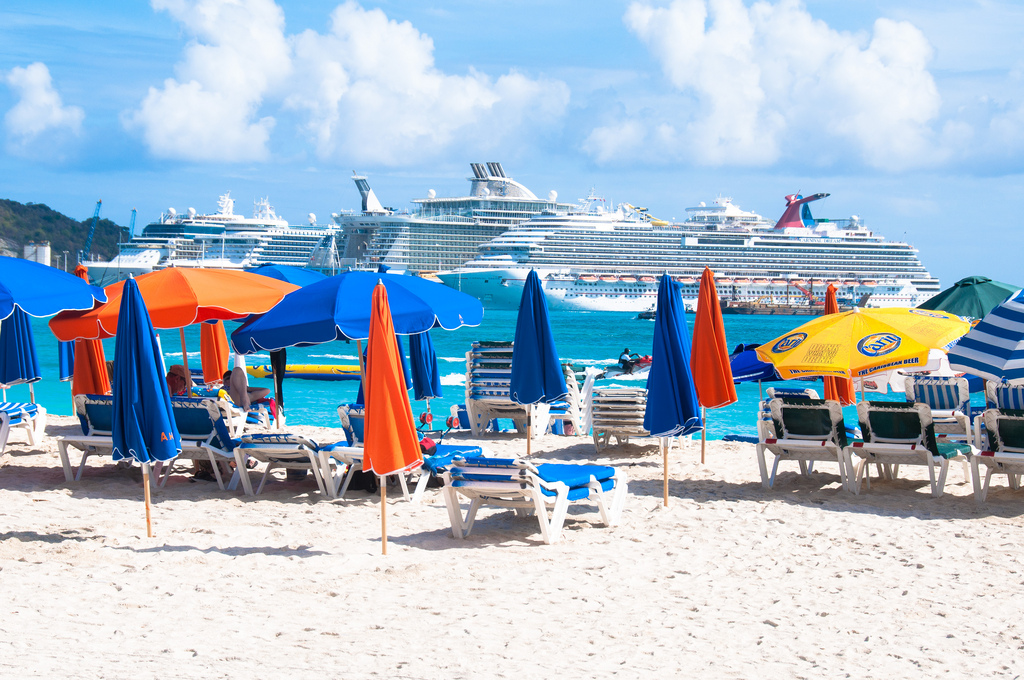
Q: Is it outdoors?
A: Yes, it is outdoors.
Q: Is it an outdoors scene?
A: Yes, it is outdoors.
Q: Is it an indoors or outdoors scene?
A: It is outdoors.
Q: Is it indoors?
A: No, it is outdoors.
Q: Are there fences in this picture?
A: No, there are no fences.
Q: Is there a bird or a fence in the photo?
A: No, there are no fences or birds.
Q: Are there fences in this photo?
A: No, there are no fences.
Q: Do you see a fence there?
A: No, there are no fences.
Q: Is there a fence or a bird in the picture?
A: No, there are no fences or birds.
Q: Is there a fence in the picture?
A: No, there are no fences.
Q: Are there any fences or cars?
A: No, there are no fences or cars.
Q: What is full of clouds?
A: The sky is full of clouds.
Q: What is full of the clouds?
A: The sky is full of clouds.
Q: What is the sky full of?
A: The sky is full of clouds.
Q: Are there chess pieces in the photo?
A: No, there are no chess pieces.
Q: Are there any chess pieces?
A: No, there are no chess pieces.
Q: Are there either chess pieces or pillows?
A: No, there are no chess pieces or pillows.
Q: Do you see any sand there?
A: Yes, there is sand.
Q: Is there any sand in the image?
A: Yes, there is sand.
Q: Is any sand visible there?
A: Yes, there is sand.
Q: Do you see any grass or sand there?
A: Yes, there is sand.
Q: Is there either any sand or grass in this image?
A: Yes, there is sand.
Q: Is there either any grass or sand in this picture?
A: Yes, there is sand.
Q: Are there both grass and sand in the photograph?
A: No, there is sand but no grass.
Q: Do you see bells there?
A: No, there are no bells.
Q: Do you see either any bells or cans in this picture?
A: No, there are no bells or cans.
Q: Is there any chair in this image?
A: Yes, there is a chair.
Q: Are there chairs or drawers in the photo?
A: Yes, there is a chair.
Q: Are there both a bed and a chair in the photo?
A: No, there is a chair but no beds.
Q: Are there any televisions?
A: No, there are no televisions.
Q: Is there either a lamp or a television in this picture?
A: No, there are no televisions or lamps.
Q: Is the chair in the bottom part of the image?
A: Yes, the chair is in the bottom of the image.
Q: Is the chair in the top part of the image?
A: No, the chair is in the bottom of the image.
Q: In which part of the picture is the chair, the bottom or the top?
A: The chair is in the bottom of the image.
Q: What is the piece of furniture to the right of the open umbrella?
A: The piece of furniture is a chair.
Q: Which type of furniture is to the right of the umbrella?
A: The piece of furniture is a chair.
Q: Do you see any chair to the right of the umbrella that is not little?
A: Yes, there is a chair to the right of the umbrella.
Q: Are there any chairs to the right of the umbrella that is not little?
A: Yes, there is a chair to the right of the umbrella.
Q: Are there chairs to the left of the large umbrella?
A: No, the chair is to the right of the umbrella.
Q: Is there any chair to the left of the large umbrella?
A: No, the chair is to the right of the umbrella.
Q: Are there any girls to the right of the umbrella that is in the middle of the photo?
A: No, there is a chair to the right of the umbrella.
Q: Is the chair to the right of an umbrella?
A: Yes, the chair is to the right of an umbrella.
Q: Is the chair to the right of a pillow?
A: No, the chair is to the right of an umbrella.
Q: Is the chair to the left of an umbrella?
A: No, the chair is to the right of an umbrella.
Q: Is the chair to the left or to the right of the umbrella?
A: The chair is to the right of the umbrella.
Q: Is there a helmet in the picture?
A: No, there are no helmets.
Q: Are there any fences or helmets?
A: No, there are no helmets or fences.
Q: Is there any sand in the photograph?
A: Yes, there is sand.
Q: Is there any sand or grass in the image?
A: Yes, there is sand.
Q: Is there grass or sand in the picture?
A: Yes, there is sand.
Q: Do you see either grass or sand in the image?
A: Yes, there is sand.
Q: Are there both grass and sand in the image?
A: No, there is sand but no grass.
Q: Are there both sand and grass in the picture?
A: No, there is sand but no grass.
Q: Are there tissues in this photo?
A: No, there are no tissues.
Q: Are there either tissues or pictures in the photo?
A: No, there are no tissues or pictures.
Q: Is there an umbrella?
A: Yes, there is an umbrella.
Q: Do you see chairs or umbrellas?
A: Yes, there is an umbrella.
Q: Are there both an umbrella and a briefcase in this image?
A: No, there is an umbrella but no briefcases.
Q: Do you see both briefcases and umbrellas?
A: No, there is an umbrella but no briefcases.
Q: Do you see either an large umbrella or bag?
A: Yes, there is a large umbrella.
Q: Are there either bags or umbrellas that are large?
A: Yes, the umbrella is large.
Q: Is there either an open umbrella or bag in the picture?
A: Yes, there is an open umbrella.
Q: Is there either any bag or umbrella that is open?
A: Yes, the umbrella is open.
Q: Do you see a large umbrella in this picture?
A: Yes, there is a large umbrella.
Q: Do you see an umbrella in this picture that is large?
A: Yes, there is an umbrella that is large.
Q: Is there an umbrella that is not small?
A: Yes, there is a large umbrella.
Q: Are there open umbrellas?
A: Yes, there is an open umbrella.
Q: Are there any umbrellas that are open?
A: Yes, there is an umbrella that is open.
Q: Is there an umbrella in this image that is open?
A: Yes, there is an umbrella that is open.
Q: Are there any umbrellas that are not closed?
A: Yes, there is a open umbrella.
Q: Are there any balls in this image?
A: No, there are no balls.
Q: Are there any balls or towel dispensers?
A: No, there are no balls or towel dispensers.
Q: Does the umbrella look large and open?
A: Yes, the umbrella is large and open.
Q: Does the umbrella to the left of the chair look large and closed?
A: No, the umbrella is large but open.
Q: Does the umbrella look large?
A: Yes, the umbrella is large.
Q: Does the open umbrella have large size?
A: Yes, the umbrella is large.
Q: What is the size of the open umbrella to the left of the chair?
A: The umbrella is large.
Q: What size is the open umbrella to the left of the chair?
A: The umbrella is large.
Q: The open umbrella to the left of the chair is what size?
A: The umbrella is large.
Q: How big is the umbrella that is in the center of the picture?
A: The umbrella is large.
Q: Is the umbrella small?
A: No, the umbrella is large.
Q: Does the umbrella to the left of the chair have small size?
A: No, the umbrella is large.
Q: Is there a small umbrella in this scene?
A: No, there is an umbrella but it is large.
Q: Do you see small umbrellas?
A: No, there is an umbrella but it is large.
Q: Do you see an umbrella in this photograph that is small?
A: No, there is an umbrella but it is large.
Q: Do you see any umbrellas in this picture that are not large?
A: No, there is an umbrella but it is large.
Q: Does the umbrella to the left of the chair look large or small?
A: The umbrella is large.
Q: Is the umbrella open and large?
A: Yes, the umbrella is open and large.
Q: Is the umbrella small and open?
A: No, the umbrella is open but large.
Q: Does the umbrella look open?
A: Yes, the umbrella is open.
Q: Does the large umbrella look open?
A: Yes, the umbrella is open.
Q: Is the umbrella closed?
A: No, the umbrella is open.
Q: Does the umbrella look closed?
A: No, the umbrella is open.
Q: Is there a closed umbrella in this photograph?
A: No, there is an umbrella but it is open.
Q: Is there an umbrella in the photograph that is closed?
A: No, there is an umbrella but it is open.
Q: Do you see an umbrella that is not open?
A: No, there is an umbrella but it is open.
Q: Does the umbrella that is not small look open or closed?
A: The umbrella is open.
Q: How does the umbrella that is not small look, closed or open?
A: The umbrella is open.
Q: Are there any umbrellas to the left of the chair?
A: Yes, there is an umbrella to the left of the chair.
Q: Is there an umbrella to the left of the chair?
A: Yes, there is an umbrella to the left of the chair.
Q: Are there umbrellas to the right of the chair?
A: No, the umbrella is to the left of the chair.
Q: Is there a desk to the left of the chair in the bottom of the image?
A: No, there is an umbrella to the left of the chair.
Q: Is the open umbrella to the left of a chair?
A: Yes, the umbrella is to the left of a chair.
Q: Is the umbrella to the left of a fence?
A: No, the umbrella is to the left of a chair.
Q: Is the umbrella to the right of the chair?
A: No, the umbrella is to the left of the chair.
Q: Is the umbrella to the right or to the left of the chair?
A: The umbrella is to the left of the chair.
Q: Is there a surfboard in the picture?
A: No, there are no surfboards.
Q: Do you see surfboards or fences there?
A: No, there are no surfboards or fences.